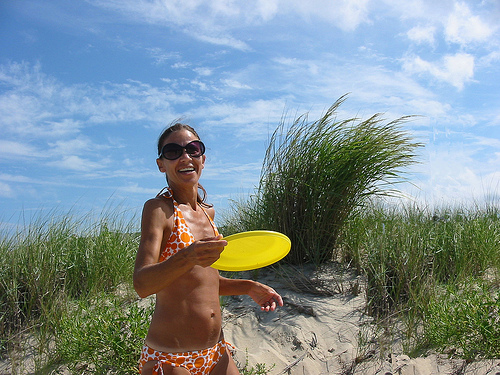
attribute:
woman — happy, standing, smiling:
[123, 122, 286, 374]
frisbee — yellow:
[203, 228, 287, 279]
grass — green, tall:
[2, 125, 496, 359]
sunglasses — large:
[161, 138, 212, 159]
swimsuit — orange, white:
[135, 200, 238, 372]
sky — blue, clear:
[2, 1, 499, 222]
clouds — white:
[2, 1, 499, 215]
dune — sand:
[6, 236, 490, 374]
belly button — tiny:
[208, 307, 218, 321]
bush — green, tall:
[233, 116, 389, 256]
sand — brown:
[8, 253, 492, 374]